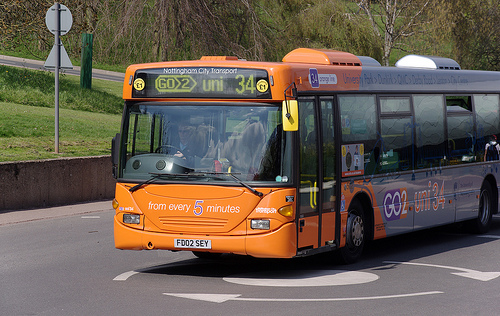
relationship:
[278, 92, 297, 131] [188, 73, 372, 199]
mirror on bus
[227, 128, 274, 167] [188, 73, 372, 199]
driver of bus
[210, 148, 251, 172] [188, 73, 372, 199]
steering wheel of bus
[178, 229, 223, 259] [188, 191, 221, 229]
plate has number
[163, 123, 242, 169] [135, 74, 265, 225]
glass in front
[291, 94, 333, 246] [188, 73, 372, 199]
door of bus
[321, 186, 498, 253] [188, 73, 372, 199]
wheels on bus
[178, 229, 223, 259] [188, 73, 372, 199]
plate of bus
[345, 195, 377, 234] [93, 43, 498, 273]
wheel at rear of bus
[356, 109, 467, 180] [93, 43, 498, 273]
windows on front of bus